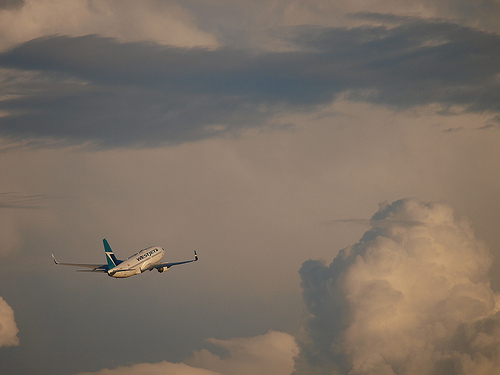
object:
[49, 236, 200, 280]
plane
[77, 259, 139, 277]
tail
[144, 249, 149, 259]
letter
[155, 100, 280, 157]
sky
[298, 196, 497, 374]
cloud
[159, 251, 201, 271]
wing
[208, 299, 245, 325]
wind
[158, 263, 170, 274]
engine